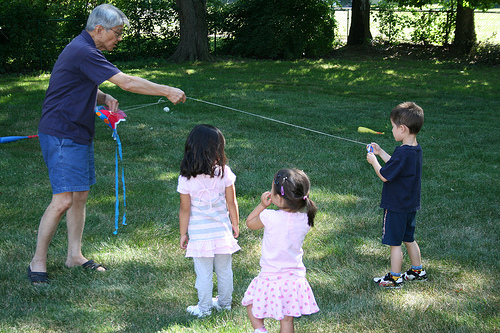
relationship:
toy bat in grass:
[355, 120, 385, 140] [314, 63, 478, 93]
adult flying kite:
[22, 0, 192, 296] [90, 92, 377, 244]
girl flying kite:
[238, 164, 323, 331] [90, 92, 377, 244]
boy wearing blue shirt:
[361, 93, 434, 288] [377, 143, 422, 213]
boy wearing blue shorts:
[361, 93, 434, 288] [380, 207, 418, 247]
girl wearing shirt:
[243, 165, 328, 331] [242, 290, 312, 319]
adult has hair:
[26, 2, 188, 289] [82, 2, 126, 26]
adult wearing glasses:
[26, 2, 188, 289] [88, 22, 133, 37]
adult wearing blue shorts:
[26, 2, 188, 289] [33, 129, 97, 195]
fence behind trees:
[325, 3, 497, 50] [246, 19, 385, 55]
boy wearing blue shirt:
[365, 100, 429, 290] [384, 158, 430, 177]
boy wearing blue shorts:
[365, 100, 429, 290] [377, 210, 417, 250]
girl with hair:
[179, 124, 240, 315] [180, 122, 226, 179]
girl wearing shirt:
[179, 124, 240, 315] [176, 165, 241, 255]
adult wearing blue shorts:
[26, 2, 188, 289] [41, 144, 88, 204]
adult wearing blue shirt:
[26, 2, 188, 289] [53, 41, 107, 131]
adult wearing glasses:
[26, 2, 188, 289] [109, 25, 128, 38]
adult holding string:
[26, 2, 188, 289] [185, 92, 368, 154]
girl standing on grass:
[238, 164, 323, 331] [9, 232, 201, 330]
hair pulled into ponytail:
[273, 166, 317, 226] [303, 194, 317, 227]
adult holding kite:
[26, 2, 188, 289] [93, 101, 129, 238]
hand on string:
[153, 83, 193, 115] [178, 86, 371, 150]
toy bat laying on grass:
[356, 125, 385, 135] [3, 60, 498, 330]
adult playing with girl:
[26, 2, 188, 289] [174, 120, 243, 319]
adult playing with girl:
[26, 2, 188, 289] [238, 164, 323, 331]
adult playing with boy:
[26, 2, 188, 289] [365, 100, 429, 290]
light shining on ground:
[183, 65, 198, 75] [7, 65, 496, 317]